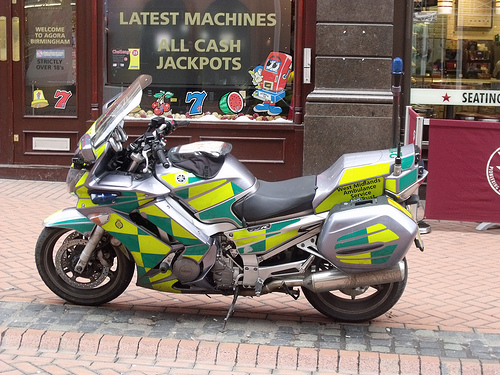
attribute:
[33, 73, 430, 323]
motorcycle — colorful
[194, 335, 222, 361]
brick — red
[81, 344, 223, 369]
brick — red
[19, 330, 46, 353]
brick — red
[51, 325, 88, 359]
brick — red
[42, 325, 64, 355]
brick — red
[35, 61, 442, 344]
bike — yellow , green 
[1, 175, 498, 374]
ground — gray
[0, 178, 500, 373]
road — red 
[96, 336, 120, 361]
brick — red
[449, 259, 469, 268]
brick — red 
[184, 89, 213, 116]
number — blue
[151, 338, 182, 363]
bricks — red